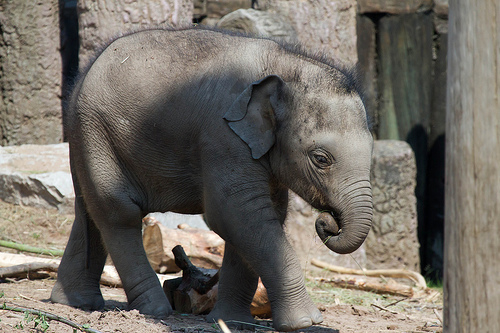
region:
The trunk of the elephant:
[321, 192, 371, 252]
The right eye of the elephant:
[310, 145, 332, 168]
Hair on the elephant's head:
[268, 49, 355, 93]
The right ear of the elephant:
[233, 77, 293, 157]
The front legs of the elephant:
[203, 181, 322, 331]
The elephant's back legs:
[56, 193, 166, 315]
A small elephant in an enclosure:
[62, 41, 374, 325]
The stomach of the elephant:
[146, 173, 196, 211]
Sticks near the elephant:
[313, 262, 421, 298]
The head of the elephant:
[279, 58, 372, 253]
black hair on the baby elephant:
[68, 13, 390, 115]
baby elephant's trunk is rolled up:
[311, 210, 380, 251]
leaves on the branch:
[0, 302, 67, 329]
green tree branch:
[2, 225, 72, 255]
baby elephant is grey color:
[57, 16, 377, 327]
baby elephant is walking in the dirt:
[37, 272, 384, 327]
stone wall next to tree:
[363, 125, 433, 277]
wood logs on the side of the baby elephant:
[138, 210, 293, 320]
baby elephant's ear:
[230, 63, 295, 165]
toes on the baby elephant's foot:
[273, 311, 333, 332]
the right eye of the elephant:
[304, 144, 337, 169]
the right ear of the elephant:
[217, 64, 304, 165]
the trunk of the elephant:
[309, 173, 379, 258]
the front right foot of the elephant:
[264, 274, 329, 329]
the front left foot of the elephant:
[202, 271, 255, 329]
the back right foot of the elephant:
[115, 263, 172, 316]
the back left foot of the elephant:
[42, 263, 109, 313]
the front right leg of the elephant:
[192, 146, 335, 330]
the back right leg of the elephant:
[65, 128, 182, 319]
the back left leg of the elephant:
[39, 190, 118, 312]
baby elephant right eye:
[305, 148, 340, 174]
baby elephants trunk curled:
[320, 194, 381, 253]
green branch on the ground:
[5, 233, 64, 263]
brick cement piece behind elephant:
[372, 128, 439, 279]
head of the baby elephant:
[219, 24, 399, 254]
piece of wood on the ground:
[160, 230, 211, 300]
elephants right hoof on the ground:
[268, 279, 335, 328]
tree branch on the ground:
[6, 298, 79, 332]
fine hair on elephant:
[68, 48, 82, 188]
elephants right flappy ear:
[235, 57, 314, 175]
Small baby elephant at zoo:
[56, 19, 395, 330]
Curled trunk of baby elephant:
[295, 213, 412, 248]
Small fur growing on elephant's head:
[276, 40, 376, 125]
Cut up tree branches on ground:
[116, 204, 439, 310]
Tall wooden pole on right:
[443, 6, 489, 329]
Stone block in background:
[279, 138, 420, 305]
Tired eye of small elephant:
[304, 145, 348, 175]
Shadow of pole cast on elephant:
[80, 88, 362, 326]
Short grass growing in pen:
[298, 272, 438, 332]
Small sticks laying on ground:
[348, 275, 451, 332]